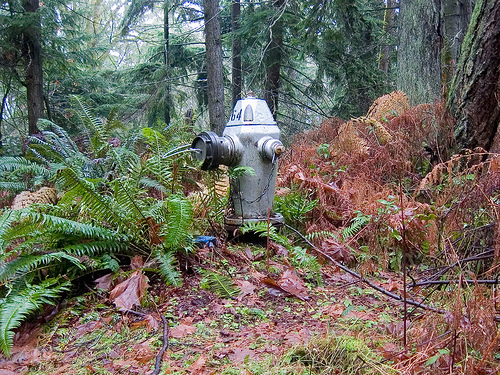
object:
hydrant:
[190, 90, 286, 244]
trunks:
[202, 0, 283, 138]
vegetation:
[277, 335, 402, 375]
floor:
[3, 284, 356, 375]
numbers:
[231, 108, 242, 121]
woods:
[0, 1, 498, 192]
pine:
[225, 0, 395, 119]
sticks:
[147, 314, 168, 374]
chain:
[229, 153, 278, 204]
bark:
[207, 55, 223, 80]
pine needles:
[353, 32, 362, 41]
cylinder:
[191, 131, 245, 171]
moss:
[446, 0, 486, 104]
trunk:
[397, 0, 442, 107]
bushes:
[0, 90, 500, 358]